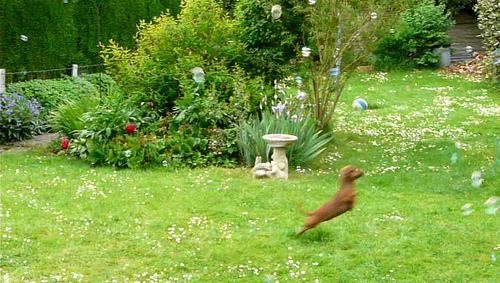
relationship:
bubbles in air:
[398, 43, 499, 242] [220, 86, 489, 195]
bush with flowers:
[1, 86, 41, 144] [7, 83, 41, 137]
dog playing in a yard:
[295, 164, 365, 238] [3, 152, 497, 281]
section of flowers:
[262, 50, 348, 124] [0, 72, 500, 283]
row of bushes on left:
[26, 61, 116, 158] [21, 102, 42, 196]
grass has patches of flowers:
[56, 177, 246, 265] [0, 72, 500, 283]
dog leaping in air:
[295, 164, 365, 238] [319, 153, 402, 270]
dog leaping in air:
[295, 164, 365, 238] [311, 157, 394, 230]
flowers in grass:
[0, 72, 500, 283] [218, 247, 322, 279]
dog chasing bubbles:
[281, 161, 375, 223] [434, 167, 498, 222]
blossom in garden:
[122, 122, 135, 134] [4, 76, 344, 186]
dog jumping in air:
[295, 164, 365, 238] [16, 12, 486, 246]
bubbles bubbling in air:
[443, 149, 499, 222] [16, 12, 486, 246]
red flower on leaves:
[123, 121, 136, 133] [82, 90, 149, 137]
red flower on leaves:
[61, 138, 68, 148] [55, 127, 94, 157]